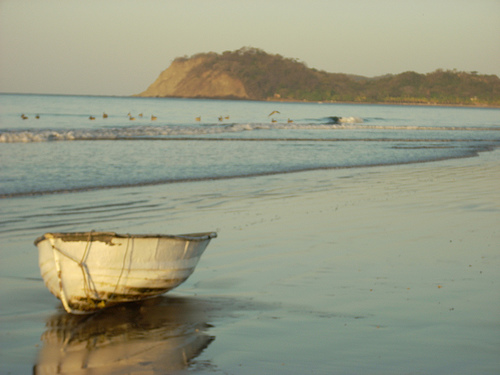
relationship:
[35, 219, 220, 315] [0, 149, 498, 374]
boat on shore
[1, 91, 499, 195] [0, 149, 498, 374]
water touching shore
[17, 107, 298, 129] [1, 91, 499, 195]
birds in water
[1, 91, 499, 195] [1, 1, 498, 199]
water in background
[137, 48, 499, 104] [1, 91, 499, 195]
hills in water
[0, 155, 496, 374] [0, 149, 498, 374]
sand on shore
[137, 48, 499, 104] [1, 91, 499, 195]
rocks in water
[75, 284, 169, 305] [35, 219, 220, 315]
dirt on boat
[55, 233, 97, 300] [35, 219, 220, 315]
ropes on boat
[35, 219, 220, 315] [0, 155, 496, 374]
boat on sand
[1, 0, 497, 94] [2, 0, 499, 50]
white clouds against sky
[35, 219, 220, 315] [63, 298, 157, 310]
boat on its keel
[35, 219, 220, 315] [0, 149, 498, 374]
boat on beach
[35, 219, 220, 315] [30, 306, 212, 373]
boat has reflection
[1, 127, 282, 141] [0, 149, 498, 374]
wave coming toward beach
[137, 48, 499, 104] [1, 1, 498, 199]
mountain in background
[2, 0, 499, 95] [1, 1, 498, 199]
sky in background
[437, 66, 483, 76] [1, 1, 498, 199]
trees in distance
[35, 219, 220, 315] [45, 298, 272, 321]
boat has shadow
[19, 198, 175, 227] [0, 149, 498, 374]
ripples on shore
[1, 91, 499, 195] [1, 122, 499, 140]
ocean has wave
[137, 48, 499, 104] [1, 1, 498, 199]
land mass in distance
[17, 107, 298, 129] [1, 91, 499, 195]
birds over water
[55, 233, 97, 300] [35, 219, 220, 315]
rope on side of boat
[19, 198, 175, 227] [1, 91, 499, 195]
ripples in water